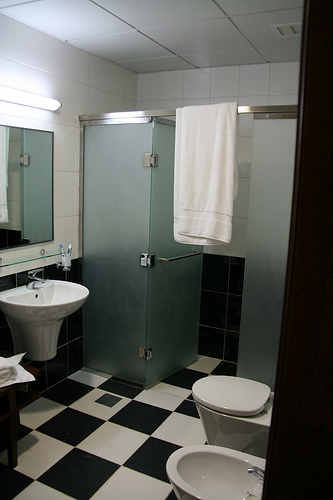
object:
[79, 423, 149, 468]
tile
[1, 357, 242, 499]
floor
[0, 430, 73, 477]
white tile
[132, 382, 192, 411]
tile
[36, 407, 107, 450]
black tile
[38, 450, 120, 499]
tile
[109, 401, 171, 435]
black tile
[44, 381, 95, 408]
tile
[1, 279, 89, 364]
bathroom sink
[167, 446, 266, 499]
bidet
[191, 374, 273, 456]
toilet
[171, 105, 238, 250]
towel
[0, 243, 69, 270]
shelf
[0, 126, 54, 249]
mirror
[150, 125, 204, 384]
shower doors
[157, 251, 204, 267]
door handle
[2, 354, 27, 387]
towels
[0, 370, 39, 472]
table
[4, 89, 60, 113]
florescent light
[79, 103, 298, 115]
shower bar